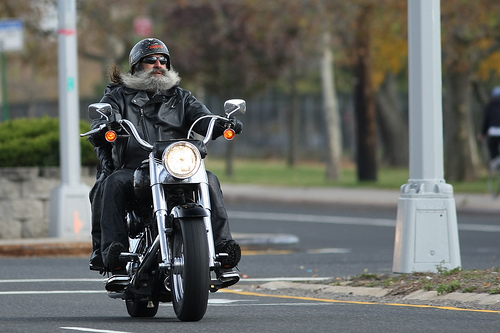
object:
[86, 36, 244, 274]
man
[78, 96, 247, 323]
motor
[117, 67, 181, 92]
beard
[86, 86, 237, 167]
leather jacket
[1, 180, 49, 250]
brick wall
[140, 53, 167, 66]
sun glasses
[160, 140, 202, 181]
headlight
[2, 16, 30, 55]
street sign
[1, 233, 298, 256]
curb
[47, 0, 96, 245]
light post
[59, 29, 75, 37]
sticker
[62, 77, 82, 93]
sticker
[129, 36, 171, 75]
motorcycle helmet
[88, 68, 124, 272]
person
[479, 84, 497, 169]
person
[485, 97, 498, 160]
outfit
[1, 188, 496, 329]
street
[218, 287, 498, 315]
line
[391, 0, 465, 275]
light post